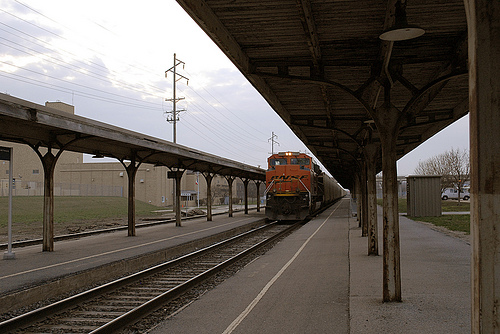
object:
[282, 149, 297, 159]
light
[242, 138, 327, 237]
train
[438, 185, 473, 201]
car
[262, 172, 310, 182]
letters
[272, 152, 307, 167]
window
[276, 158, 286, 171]
paper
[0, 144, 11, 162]
flag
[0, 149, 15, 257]
pole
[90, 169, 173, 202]
building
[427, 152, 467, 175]
tree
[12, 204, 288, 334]
tracks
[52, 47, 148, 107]
line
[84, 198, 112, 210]
grass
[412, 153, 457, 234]
background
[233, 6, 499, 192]
bridge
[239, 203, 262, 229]
gravel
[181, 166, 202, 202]
fence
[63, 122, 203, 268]
side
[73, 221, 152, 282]
line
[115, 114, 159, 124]
sky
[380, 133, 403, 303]
pillar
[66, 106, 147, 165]
roof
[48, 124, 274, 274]
station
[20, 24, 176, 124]
wire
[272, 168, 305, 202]
front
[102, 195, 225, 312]
platform